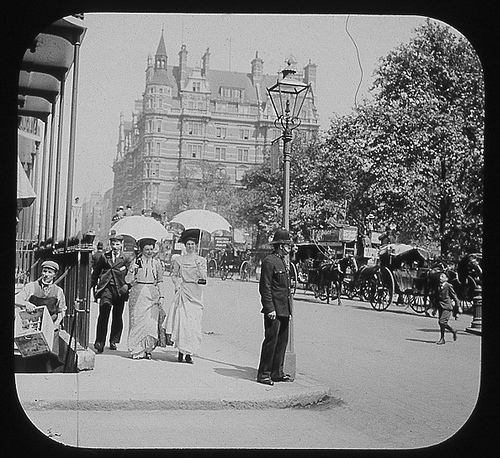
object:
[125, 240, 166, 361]
woman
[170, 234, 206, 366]
woman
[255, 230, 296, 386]
man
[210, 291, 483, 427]
street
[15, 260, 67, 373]
man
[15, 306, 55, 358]
crate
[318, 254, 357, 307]
horse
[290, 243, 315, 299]
carriage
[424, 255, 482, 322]
horse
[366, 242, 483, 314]
carriage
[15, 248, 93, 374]
stairs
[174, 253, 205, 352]
dress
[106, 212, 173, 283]
umbrella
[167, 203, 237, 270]
umbrella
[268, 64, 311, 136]
light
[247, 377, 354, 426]
corner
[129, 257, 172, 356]
dress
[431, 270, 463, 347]
boy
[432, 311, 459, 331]
knickers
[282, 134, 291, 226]
post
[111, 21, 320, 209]
building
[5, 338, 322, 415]
sidewalk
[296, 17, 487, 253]
trees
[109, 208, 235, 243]
umbrellas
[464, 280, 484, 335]
hydrant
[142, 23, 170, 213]
tower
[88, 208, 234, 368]
crowd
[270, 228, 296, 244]
hat